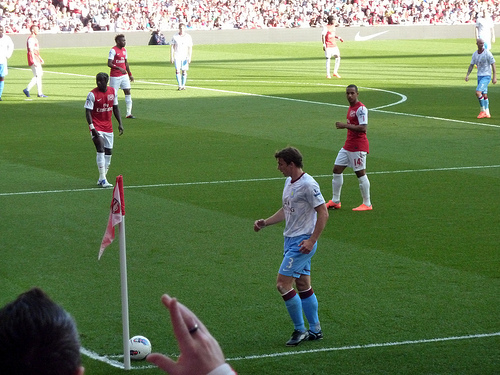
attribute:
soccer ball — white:
[131, 333, 160, 368]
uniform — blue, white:
[474, 57, 487, 93]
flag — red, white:
[80, 179, 139, 318]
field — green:
[38, 124, 489, 374]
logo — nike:
[351, 28, 402, 52]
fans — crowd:
[233, 1, 430, 24]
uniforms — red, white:
[85, 53, 138, 162]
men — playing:
[25, 27, 155, 186]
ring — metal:
[189, 325, 206, 336]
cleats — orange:
[330, 197, 383, 214]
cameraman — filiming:
[13, 291, 100, 366]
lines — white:
[237, 70, 447, 125]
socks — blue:
[287, 294, 320, 326]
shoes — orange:
[474, 113, 494, 122]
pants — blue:
[476, 78, 493, 97]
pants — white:
[114, 74, 135, 88]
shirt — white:
[281, 180, 322, 228]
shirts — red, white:
[86, 63, 133, 117]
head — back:
[22, 299, 64, 354]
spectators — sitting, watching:
[80, 3, 337, 29]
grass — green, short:
[147, 106, 320, 176]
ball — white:
[132, 328, 145, 352]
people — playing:
[25, 24, 487, 230]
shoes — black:
[287, 321, 331, 343]